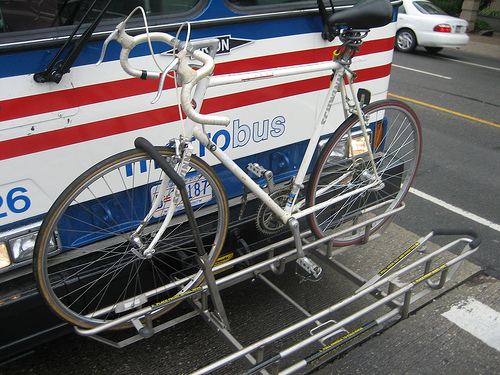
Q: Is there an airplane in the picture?
A: No, there are no airplanes.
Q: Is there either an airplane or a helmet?
A: No, there are no airplanes or helmets.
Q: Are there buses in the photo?
A: Yes, there is a bus.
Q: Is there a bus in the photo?
A: Yes, there is a bus.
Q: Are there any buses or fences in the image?
A: Yes, there is a bus.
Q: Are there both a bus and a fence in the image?
A: No, there is a bus but no fences.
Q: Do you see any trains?
A: No, there are no trains.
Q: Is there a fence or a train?
A: No, there are no trains or fences.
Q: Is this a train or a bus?
A: This is a bus.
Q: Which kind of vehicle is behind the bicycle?
A: The vehicle is a bus.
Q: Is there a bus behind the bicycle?
A: Yes, there is a bus behind the bicycle.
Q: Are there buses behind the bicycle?
A: Yes, there is a bus behind the bicycle.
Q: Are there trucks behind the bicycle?
A: No, there is a bus behind the bicycle.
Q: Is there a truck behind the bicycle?
A: No, there is a bus behind the bicycle.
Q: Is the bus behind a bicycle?
A: Yes, the bus is behind a bicycle.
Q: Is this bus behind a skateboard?
A: No, the bus is behind a bicycle.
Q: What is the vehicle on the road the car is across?
A: The vehicle is a bus.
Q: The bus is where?
A: The bus is on the road.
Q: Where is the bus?
A: The bus is on the road.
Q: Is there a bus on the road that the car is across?
A: Yes, there is a bus on the road.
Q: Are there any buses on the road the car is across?
A: Yes, there is a bus on the road.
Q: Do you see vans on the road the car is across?
A: No, there is a bus on the road.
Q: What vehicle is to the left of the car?
A: The vehicle is a bus.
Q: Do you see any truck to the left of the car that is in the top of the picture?
A: No, there is a bus to the left of the car.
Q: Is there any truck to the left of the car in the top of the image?
A: No, there is a bus to the left of the car.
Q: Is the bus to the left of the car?
A: Yes, the bus is to the left of the car.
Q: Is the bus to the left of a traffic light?
A: No, the bus is to the left of the car.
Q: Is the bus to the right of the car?
A: No, the bus is to the left of the car.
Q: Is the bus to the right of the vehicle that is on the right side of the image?
A: No, the bus is to the left of the car.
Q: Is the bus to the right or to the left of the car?
A: The bus is to the left of the car.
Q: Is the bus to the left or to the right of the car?
A: The bus is to the left of the car.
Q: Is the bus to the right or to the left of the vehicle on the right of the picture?
A: The bus is to the left of the car.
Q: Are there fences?
A: No, there are no fences.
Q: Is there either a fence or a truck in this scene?
A: No, there are no fences or trucks.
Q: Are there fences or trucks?
A: No, there are no fences or trucks.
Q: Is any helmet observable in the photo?
A: No, there are no helmets.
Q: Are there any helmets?
A: No, there are no helmets.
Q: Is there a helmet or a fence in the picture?
A: No, there are no helmets or fences.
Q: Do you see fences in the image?
A: No, there are no fences.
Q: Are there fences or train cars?
A: No, there are no fences or train cars.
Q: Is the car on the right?
A: Yes, the car is on the right of the image.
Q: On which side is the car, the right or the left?
A: The car is on the right of the image.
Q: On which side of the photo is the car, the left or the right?
A: The car is on the right of the image.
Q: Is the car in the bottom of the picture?
A: No, the car is in the top of the image.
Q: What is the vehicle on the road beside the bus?
A: The vehicle is a car.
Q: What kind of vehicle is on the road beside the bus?
A: The vehicle is a car.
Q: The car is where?
A: The car is on the road.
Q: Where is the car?
A: The car is on the road.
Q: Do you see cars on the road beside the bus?
A: Yes, there is a car on the road.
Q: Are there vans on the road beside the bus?
A: No, there is a car on the road.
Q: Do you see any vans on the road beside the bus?
A: No, there is a car on the road.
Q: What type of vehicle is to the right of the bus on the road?
A: The vehicle is a car.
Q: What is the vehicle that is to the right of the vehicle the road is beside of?
A: The vehicle is a car.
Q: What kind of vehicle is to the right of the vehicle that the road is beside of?
A: The vehicle is a car.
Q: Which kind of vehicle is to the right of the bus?
A: The vehicle is a car.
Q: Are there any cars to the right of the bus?
A: Yes, there is a car to the right of the bus.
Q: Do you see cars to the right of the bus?
A: Yes, there is a car to the right of the bus.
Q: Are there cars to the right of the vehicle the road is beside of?
A: Yes, there is a car to the right of the bus.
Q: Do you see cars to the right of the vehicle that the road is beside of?
A: Yes, there is a car to the right of the bus.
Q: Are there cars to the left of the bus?
A: No, the car is to the right of the bus.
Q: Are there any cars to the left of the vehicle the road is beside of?
A: No, the car is to the right of the bus.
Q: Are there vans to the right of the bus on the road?
A: No, there is a car to the right of the bus.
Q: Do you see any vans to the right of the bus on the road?
A: No, there is a car to the right of the bus.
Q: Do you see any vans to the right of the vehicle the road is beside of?
A: No, there is a car to the right of the bus.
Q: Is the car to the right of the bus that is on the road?
A: Yes, the car is to the right of the bus.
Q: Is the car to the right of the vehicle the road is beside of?
A: Yes, the car is to the right of the bus.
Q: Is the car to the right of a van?
A: No, the car is to the right of the bus.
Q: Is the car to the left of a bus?
A: No, the car is to the right of a bus.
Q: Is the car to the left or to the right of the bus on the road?
A: The car is to the right of the bus.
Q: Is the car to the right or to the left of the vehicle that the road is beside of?
A: The car is to the right of the bus.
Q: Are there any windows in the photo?
A: Yes, there is a window.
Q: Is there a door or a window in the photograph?
A: Yes, there is a window.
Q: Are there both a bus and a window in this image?
A: Yes, there are both a window and a bus.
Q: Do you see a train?
A: No, there are no trains.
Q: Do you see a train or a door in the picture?
A: No, there are no trains or doors.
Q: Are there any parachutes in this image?
A: No, there are no parachutes.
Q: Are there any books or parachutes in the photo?
A: No, there are no parachutes or books.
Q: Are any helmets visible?
A: No, there are no helmets.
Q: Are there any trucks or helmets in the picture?
A: No, there are no helmets or trucks.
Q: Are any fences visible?
A: No, there are no fences.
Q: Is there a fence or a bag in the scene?
A: No, there are no fences or bags.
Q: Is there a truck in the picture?
A: No, there are no trucks.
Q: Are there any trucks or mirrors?
A: No, there are no trucks or mirrors.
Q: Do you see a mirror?
A: No, there are no mirrors.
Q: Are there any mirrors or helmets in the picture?
A: No, there are no mirrors or helmets.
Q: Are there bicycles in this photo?
A: Yes, there is a bicycle.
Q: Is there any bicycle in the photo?
A: Yes, there is a bicycle.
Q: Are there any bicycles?
A: Yes, there is a bicycle.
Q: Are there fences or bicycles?
A: Yes, there is a bicycle.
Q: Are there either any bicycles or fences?
A: Yes, there is a bicycle.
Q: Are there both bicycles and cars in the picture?
A: Yes, there are both a bicycle and a car.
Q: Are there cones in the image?
A: No, there are no cones.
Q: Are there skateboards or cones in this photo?
A: No, there are no cones or skateboards.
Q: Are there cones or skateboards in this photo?
A: No, there are no cones or skateboards.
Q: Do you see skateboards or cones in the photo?
A: No, there are no cones or skateboards.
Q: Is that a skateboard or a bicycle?
A: That is a bicycle.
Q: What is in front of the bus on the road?
A: The bicycle is in front of the bus.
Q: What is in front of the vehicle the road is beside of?
A: The bicycle is in front of the bus.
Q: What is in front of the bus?
A: The bicycle is in front of the bus.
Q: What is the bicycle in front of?
A: The bicycle is in front of the bus.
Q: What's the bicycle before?
A: The bicycle is in front of the bus.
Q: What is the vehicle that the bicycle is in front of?
A: The vehicle is a bus.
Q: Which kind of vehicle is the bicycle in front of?
A: The bicycle is in front of the bus.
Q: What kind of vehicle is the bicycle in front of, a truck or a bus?
A: The bicycle is in front of a bus.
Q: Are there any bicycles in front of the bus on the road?
A: Yes, there is a bicycle in front of the bus.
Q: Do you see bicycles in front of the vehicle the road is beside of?
A: Yes, there is a bicycle in front of the bus.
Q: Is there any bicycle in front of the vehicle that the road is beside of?
A: Yes, there is a bicycle in front of the bus.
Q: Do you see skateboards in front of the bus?
A: No, there is a bicycle in front of the bus.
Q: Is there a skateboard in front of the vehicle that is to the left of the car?
A: No, there is a bicycle in front of the bus.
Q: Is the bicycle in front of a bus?
A: Yes, the bicycle is in front of a bus.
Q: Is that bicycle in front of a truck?
A: No, the bicycle is in front of a bus.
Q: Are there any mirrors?
A: No, there are no mirrors.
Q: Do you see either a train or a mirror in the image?
A: No, there are no mirrors or trains.